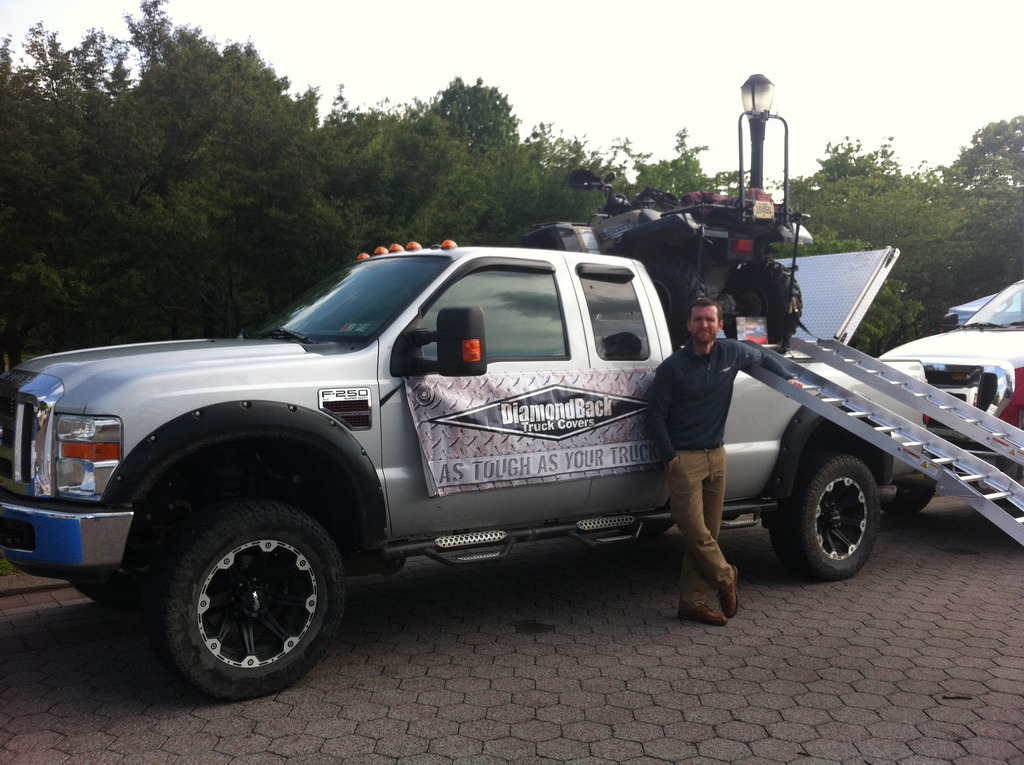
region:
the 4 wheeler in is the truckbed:
[571, 161, 819, 377]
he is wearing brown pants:
[678, 462, 711, 523]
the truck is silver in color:
[116, 358, 194, 394]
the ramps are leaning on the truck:
[726, 312, 989, 467]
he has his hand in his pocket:
[650, 432, 692, 486]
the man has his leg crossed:
[676, 499, 747, 636]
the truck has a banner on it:
[386, 351, 693, 504]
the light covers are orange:
[350, 237, 468, 260]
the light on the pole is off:
[720, 58, 791, 160]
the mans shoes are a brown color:
[680, 569, 750, 633]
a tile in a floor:
[302, 667, 353, 696]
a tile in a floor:
[311, 698, 389, 731]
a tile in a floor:
[416, 715, 445, 738]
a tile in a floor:
[454, 702, 500, 748]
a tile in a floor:
[458, 657, 504, 684]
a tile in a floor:
[527, 685, 600, 724]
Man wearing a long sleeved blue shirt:
[633, 286, 811, 474]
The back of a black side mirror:
[375, 289, 489, 384]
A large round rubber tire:
[127, 478, 358, 712]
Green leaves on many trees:
[2, 1, 1022, 365]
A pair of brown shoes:
[662, 552, 739, 626]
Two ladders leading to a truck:
[721, 318, 1013, 552]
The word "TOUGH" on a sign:
[457, 444, 531, 480]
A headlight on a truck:
[39, 393, 129, 505]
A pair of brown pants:
[656, 433, 746, 621]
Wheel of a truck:
[150, 507, 350, 703]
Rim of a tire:
[207, 544, 305, 655]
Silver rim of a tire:
[210, 544, 305, 653]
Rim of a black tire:
[203, 542, 314, 664]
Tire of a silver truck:
[157, 506, 345, 694]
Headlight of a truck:
[43, 405, 123, 505]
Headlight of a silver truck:
[51, 402, 127, 502]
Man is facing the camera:
[645, 299, 816, 632]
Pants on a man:
[668, 443, 744, 608]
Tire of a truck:
[147, 500, 343, 701]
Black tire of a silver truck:
[146, 490, 353, 707]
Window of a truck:
[583, 272, 650, 364]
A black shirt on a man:
[646, 335, 787, 450]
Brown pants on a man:
[675, 440, 732, 590]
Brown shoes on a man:
[680, 563, 745, 627]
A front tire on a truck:
[146, 493, 347, 693]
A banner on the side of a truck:
[402, 367, 668, 495]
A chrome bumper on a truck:
[2, 493, 138, 580]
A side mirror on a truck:
[408, 309, 489, 383]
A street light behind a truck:
[728, 70, 792, 187]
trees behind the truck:
[18, 25, 999, 253]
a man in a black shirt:
[664, 320, 750, 622]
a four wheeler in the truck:
[558, 180, 803, 313]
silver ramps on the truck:
[752, 310, 1009, 546]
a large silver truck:
[27, 250, 925, 643]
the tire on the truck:
[164, 511, 343, 686]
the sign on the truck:
[411, 380, 702, 510]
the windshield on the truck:
[307, 268, 410, 333]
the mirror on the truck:
[424, 300, 489, 368]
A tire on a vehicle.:
[151, 492, 349, 699]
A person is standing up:
[647, 296, 803, 626]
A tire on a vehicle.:
[768, 447, 882, 577]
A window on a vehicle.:
[419, 264, 572, 363]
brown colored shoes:
[678, 579, 745, 628]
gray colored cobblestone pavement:
[0, 493, 1022, 759]